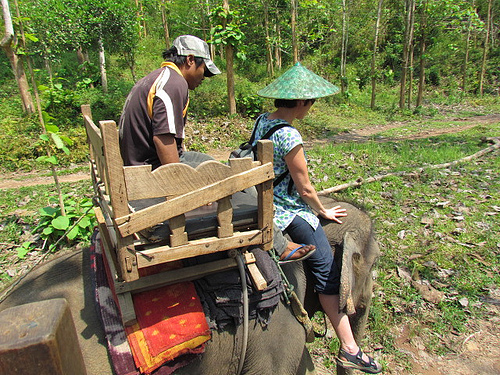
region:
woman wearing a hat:
[243, 57, 380, 374]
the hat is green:
[252, 59, 342, 103]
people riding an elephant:
[1, 4, 396, 373]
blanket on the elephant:
[81, 239, 215, 373]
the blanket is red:
[124, 276, 216, 373]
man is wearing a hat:
[115, 32, 316, 266]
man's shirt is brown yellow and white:
[118, 60, 192, 170]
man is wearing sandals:
[275, 231, 318, 263]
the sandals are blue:
[272, 237, 316, 264]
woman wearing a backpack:
[227, 114, 292, 164]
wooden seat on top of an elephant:
[73, 101, 278, 284]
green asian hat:
[253, 58, 343, 106]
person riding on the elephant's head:
[234, 59, 388, 374]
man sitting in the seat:
[97, 27, 317, 271]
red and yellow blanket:
[86, 215, 214, 366]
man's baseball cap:
[165, 32, 224, 81]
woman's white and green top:
[247, 112, 328, 234]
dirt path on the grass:
[0, 100, 498, 189]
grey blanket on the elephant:
[186, 240, 295, 331]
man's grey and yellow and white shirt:
[106, 56, 197, 179]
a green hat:
[250, 56, 345, 111]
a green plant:
[19, 188, 96, 237]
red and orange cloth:
[113, 283, 225, 362]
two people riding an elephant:
[16, 25, 423, 362]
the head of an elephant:
[314, 201, 397, 345]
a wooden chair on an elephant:
[68, 101, 298, 268]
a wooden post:
[7, 302, 103, 372]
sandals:
[327, 343, 396, 372]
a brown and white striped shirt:
[110, 53, 214, 163]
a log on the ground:
[322, 128, 499, 198]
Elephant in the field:
[0, 192, 382, 373]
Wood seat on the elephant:
[78, 102, 276, 324]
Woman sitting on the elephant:
[247, 57, 385, 374]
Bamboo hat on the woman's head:
[259, 59, 341, 99]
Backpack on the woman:
[228, 115, 298, 198]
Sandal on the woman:
[333, 347, 383, 374]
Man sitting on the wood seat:
[110, 34, 318, 264]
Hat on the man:
[171, 34, 223, 78]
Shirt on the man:
[121, 61, 190, 163]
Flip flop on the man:
[281, 242, 318, 264]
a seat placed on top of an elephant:
[82, 101, 279, 293]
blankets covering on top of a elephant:
[88, 266, 273, 369]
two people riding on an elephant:
[108, 23, 399, 210]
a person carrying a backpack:
[223, 125, 262, 184]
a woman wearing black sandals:
[323, 334, 375, 374]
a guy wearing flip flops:
[260, 220, 308, 271]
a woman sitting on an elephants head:
[233, 111, 360, 285]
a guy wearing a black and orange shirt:
[97, 62, 249, 151]